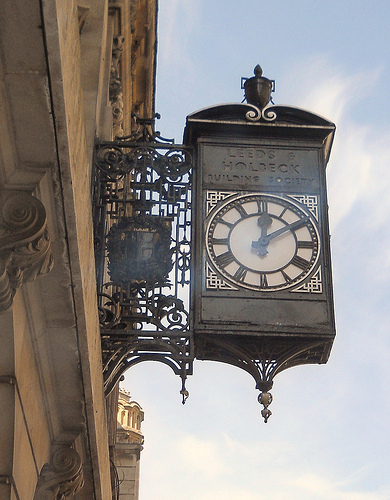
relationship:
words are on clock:
[208, 149, 311, 185] [224, 206, 313, 275]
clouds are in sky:
[307, 37, 363, 104] [165, 42, 371, 227]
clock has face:
[202, 189, 326, 301] [212, 194, 319, 291]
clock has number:
[202, 189, 326, 301] [291, 255, 309, 269]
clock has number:
[202, 189, 326, 301] [298, 240, 314, 248]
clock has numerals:
[202, 189, 326, 301] [260, 273, 268, 287]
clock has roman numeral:
[202, 189, 326, 301] [210, 247, 237, 271]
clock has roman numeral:
[202, 189, 326, 301] [208, 234, 235, 247]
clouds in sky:
[119, 12, 390, 431] [307, 17, 362, 77]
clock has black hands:
[198, 185, 329, 299] [252, 211, 274, 256]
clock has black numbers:
[202, 189, 326, 301] [207, 203, 242, 248]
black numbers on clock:
[257, 199, 268, 212] [202, 189, 326, 301]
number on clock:
[276, 202, 292, 221] [202, 189, 326, 301]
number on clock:
[290, 215, 308, 233] [202, 189, 326, 301]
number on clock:
[291, 234, 316, 251] [202, 189, 326, 301]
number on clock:
[289, 256, 312, 273] [202, 189, 326, 301]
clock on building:
[202, 189, 326, 301] [2, 1, 163, 498]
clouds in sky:
[119, 12, 390, 431] [274, 7, 388, 175]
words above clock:
[205, 144, 305, 190] [201, 138, 327, 312]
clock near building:
[202, 189, 326, 301] [18, 0, 101, 452]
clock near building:
[202, 189, 326, 301] [2, 1, 163, 498]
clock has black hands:
[202, 189, 326, 301] [252, 211, 274, 256]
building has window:
[3, 88, 329, 478] [110, 40, 154, 109]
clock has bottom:
[202, 189, 326, 301] [192, 329, 336, 431]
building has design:
[3, 0, 336, 500] [32, 432, 104, 488]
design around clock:
[201, 182, 326, 296] [151, 166, 351, 330]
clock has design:
[202, 189, 326, 301] [242, 96, 278, 124]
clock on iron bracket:
[202, 189, 326, 301] [93, 106, 189, 380]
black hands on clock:
[252, 212, 313, 258] [198, 185, 329, 299]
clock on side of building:
[202, 189, 326, 301] [0, 78, 149, 384]